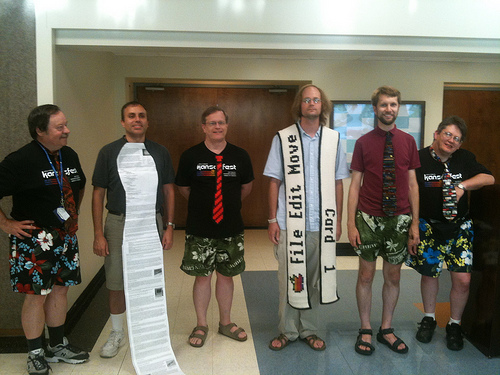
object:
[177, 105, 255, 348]
man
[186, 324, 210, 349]
sandals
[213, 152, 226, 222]
tie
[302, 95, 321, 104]
glasses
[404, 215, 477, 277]
shorts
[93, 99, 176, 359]
man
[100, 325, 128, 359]
sneakers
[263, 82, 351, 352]
man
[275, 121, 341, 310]
scarf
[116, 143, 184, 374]
paper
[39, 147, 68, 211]
necklace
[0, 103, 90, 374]
man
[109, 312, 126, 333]
socks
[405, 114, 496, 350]
men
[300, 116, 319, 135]
neck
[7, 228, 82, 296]
shorts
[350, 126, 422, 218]
shirt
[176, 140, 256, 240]
t-shirt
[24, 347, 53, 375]
tennis shoes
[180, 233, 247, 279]
bottoms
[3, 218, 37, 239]
hand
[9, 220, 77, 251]
hips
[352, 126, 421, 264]
clothing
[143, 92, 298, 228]
door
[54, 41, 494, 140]
background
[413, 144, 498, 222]
shirt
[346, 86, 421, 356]
man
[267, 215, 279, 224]
watch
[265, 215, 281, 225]
wrist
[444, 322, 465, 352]
shoes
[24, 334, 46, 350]
socks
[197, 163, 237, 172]
symbol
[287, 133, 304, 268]
file edit move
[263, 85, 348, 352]
something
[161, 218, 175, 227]
wristwatch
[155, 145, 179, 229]
arm